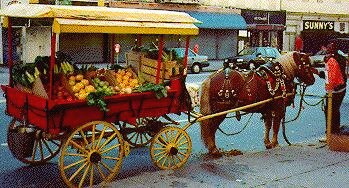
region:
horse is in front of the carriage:
[1, 2, 317, 187]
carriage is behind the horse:
[3, 4, 318, 185]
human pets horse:
[193, 39, 346, 166]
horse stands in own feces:
[195, 50, 315, 163]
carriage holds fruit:
[1, 4, 201, 187]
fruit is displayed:
[8, 48, 189, 114]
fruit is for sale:
[6, 43, 187, 117]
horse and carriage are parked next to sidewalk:
[1, 2, 312, 187]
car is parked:
[157, 43, 213, 74]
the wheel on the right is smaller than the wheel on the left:
[56, 117, 191, 186]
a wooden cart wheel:
[59, 118, 125, 185]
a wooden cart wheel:
[149, 125, 190, 167]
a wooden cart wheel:
[124, 117, 153, 145]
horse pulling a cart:
[198, 49, 314, 157]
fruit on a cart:
[68, 71, 96, 101]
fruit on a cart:
[116, 66, 139, 91]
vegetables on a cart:
[55, 54, 74, 71]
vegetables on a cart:
[10, 55, 46, 81]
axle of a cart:
[90, 151, 100, 164]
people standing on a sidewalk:
[321, 45, 346, 136]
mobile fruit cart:
[3, 0, 348, 187]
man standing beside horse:
[5, 0, 343, 162]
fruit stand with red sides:
[0, 1, 214, 166]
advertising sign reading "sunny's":
[294, 19, 347, 47]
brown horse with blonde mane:
[199, 44, 323, 159]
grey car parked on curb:
[154, 40, 210, 77]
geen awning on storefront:
[117, 1, 258, 65]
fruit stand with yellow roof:
[2, 1, 205, 187]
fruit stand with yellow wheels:
[0, 3, 248, 186]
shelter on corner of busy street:
[248, 16, 295, 62]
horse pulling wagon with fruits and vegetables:
[1, 40, 307, 182]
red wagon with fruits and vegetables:
[1, 44, 244, 178]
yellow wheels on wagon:
[0, 63, 204, 186]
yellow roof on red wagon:
[3, 3, 212, 126]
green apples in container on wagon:
[82, 67, 122, 150]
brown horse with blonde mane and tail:
[193, 43, 320, 143]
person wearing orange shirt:
[311, 24, 347, 162]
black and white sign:
[298, 17, 339, 35]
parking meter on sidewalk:
[93, 37, 125, 70]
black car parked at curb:
[218, 40, 307, 76]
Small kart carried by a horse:
[3, 3, 314, 186]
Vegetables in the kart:
[10, 51, 170, 111]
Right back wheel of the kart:
[58, 122, 126, 184]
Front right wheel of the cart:
[149, 128, 191, 172]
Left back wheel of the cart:
[6, 117, 59, 163]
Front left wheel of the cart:
[121, 111, 153, 146]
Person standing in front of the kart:
[319, 44, 343, 146]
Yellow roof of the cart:
[3, 2, 203, 35]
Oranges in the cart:
[66, 70, 92, 102]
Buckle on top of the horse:
[216, 46, 290, 103]